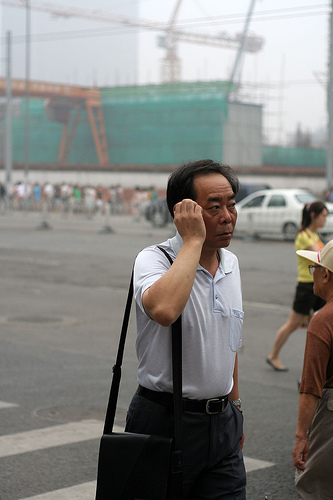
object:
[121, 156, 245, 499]
man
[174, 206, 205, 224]
phone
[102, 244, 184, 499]
satchel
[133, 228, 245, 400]
shirt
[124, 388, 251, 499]
pants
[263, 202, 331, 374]
woman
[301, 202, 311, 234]
pony-tail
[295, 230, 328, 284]
shirt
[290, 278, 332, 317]
skirt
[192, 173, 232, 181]
hairline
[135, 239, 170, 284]
shoulder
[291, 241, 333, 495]
man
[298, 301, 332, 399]
shirt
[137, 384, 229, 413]
belt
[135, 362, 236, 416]
waist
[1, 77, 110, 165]
structure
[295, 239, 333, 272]
cap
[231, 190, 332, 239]
car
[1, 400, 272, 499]
lines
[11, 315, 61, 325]
cover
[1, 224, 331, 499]
road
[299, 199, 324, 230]
hair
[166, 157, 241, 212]
hair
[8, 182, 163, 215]
people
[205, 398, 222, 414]
buckle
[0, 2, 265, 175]
crane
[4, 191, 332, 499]
area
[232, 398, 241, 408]
watch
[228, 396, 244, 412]
wrist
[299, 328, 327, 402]
sleeve